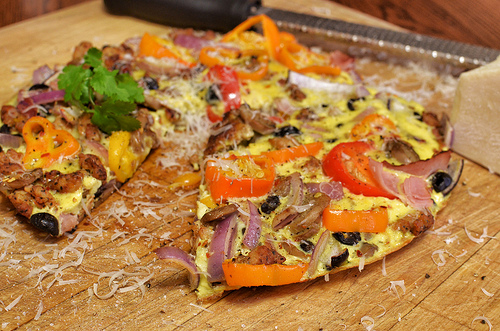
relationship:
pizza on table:
[54, 32, 453, 279] [45, 22, 121, 31]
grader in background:
[259, 4, 499, 72] [0, 13, 490, 71]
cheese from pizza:
[108, 203, 167, 237] [54, 32, 453, 279]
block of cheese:
[446, 59, 498, 166] [108, 203, 167, 237]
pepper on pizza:
[20, 119, 77, 170] [54, 32, 453, 279]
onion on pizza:
[209, 211, 237, 278] [54, 32, 453, 279]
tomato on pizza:
[325, 137, 393, 205] [54, 32, 453, 279]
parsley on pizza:
[58, 50, 148, 131] [54, 32, 453, 279]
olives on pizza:
[27, 211, 63, 235] [54, 32, 453, 279]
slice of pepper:
[45, 131, 68, 150] [20, 119, 77, 170]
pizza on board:
[54, 32, 453, 279] [41, 265, 322, 329]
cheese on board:
[108, 203, 167, 237] [41, 265, 322, 329]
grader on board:
[259, 4, 499, 72] [41, 265, 322, 329]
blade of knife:
[318, 18, 498, 63] [259, 4, 499, 72]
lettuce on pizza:
[87, 95, 141, 123] [54, 32, 453, 279]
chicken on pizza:
[210, 108, 272, 146] [54, 32, 453, 279]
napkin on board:
[455, 52, 499, 107] [41, 265, 322, 329]